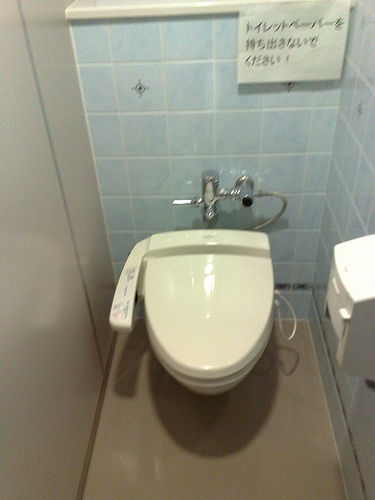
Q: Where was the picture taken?
A: A bathroom.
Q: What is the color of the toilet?
A: White.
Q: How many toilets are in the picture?
A: One.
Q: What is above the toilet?
A: A sign.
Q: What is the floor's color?
A: Brown.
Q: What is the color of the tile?
A: Blue.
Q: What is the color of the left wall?
A: Brown.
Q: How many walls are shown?
A: Three.